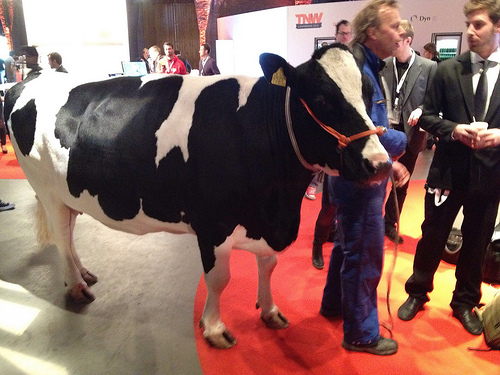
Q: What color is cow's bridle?
A: Red.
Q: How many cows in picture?
A: One.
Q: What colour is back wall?
A: White.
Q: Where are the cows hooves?
A: Ground.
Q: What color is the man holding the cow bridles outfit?
A: Blue.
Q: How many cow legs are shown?
A: Four.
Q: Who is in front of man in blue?
A: Man in black and white suit.